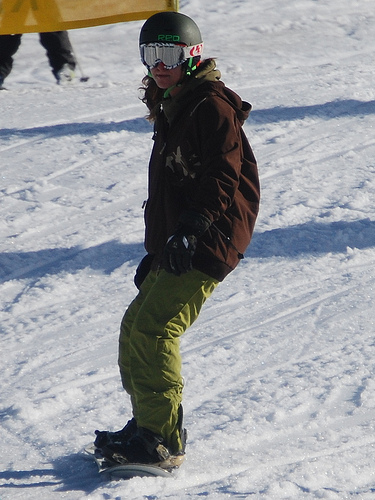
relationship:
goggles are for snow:
[133, 38, 203, 74] [9, 6, 374, 485]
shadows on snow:
[256, 79, 374, 275] [9, 6, 374, 485]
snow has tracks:
[9, 6, 374, 485] [203, 280, 360, 477]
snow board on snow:
[90, 418, 193, 485] [9, 6, 374, 485]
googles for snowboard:
[133, 38, 203, 74] [90, 418, 193, 485]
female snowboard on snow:
[72, 0, 276, 490] [9, 6, 374, 485]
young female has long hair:
[72, 0, 276, 490] [118, 67, 180, 151]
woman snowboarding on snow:
[72, 0, 276, 490] [9, 6, 374, 485]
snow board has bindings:
[96, 447, 191, 484] [93, 410, 194, 461]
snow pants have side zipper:
[105, 247, 222, 444] [165, 386, 194, 458]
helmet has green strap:
[132, 6, 212, 56] [180, 59, 198, 80]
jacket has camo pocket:
[123, 61, 269, 291] [133, 189, 169, 230]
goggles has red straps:
[133, 38, 203, 74] [185, 38, 210, 63]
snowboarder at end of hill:
[72, 0, 276, 490] [9, 265, 374, 496]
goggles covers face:
[133, 38, 203, 74] [133, 38, 192, 96]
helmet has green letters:
[132, 6, 212, 56] [147, 27, 192, 49]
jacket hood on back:
[202, 59, 267, 132] [199, 60, 282, 253]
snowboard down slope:
[72, 0, 276, 490] [9, 265, 374, 496]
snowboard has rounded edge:
[96, 447, 191, 484] [92, 454, 169, 479]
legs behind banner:
[0, 1, 92, 96] [0, 2, 189, 38]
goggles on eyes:
[133, 38, 203, 74] [138, 45, 183, 67]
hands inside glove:
[122, 227, 210, 292] [149, 223, 217, 291]